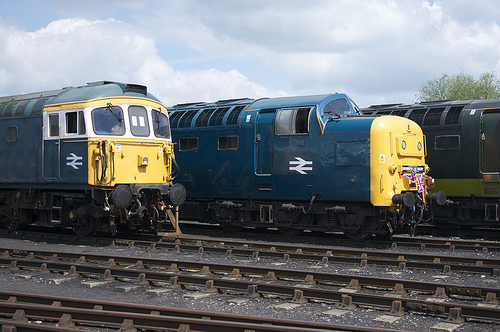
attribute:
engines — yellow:
[184, 96, 438, 248]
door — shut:
[252, 101, 278, 176]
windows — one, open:
[43, 99, 460, 139]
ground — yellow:
[323, 191, 341, 222]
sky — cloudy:
[271, 26, 346, 38]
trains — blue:
[0, 50, 420, 245]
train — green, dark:
[385, 97, 498, 221]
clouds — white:
[0, 0, 500, 105]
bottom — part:
[188, 200, 409, 247]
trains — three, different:
[57, 52, 450, 309]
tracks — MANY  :
[16, 211, 498, 318]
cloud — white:
[0, 5, 168, 80]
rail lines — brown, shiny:
[7, 286, 275, 330]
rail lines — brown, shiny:
[7, 242, 497, 317]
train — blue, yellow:
[22, 71, 176, 218]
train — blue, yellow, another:
[161, 90, 453, 248]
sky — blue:
[0, 2, 499, 106]